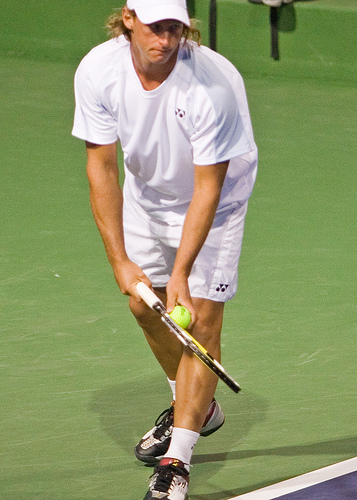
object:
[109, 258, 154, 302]
hand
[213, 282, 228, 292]
brand logo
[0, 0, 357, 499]
court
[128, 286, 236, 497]
legs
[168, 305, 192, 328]
ball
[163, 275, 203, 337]
hands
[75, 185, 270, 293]
shorts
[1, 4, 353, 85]
wall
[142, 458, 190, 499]
sneaker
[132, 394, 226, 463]
sneaker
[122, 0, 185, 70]
head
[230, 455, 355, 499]
boundary line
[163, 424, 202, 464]
sock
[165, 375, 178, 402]
sock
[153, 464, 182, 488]
shoe lace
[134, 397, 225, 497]
shoes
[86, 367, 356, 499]
shadow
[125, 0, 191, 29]
cap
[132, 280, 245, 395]
racket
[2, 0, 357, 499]
tennis court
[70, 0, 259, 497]
man